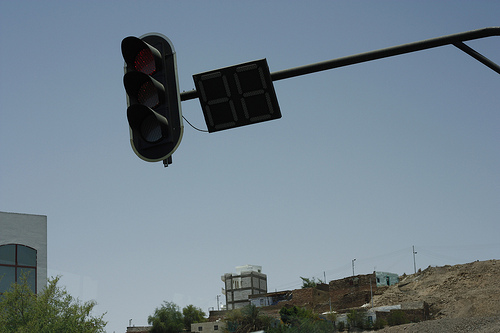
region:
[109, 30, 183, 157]
row of three lights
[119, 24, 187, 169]
black cones around the lights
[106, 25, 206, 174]
traffic light on a pole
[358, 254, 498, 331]
dirt on the ground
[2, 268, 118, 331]
top of a tree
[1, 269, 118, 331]
green leaves on the tree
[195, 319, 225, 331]
two small windows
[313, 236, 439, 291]
power lines on top of the incline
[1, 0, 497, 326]
no clouds visible in the sky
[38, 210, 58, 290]
corner of the building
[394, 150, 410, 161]
part of the sky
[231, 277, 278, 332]
part of a house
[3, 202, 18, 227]
side of a wall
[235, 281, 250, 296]
side of a building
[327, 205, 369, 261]
part of a cloud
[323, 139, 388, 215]
part of a cloud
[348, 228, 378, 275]
[art f a cloud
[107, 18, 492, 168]
pole with traffic lights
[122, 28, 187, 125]
three traffic lights on panel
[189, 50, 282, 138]
panel for lit numbers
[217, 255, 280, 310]
building on elevated terrain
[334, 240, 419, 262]
utility lines strung between poles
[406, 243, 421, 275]
poles with utility lines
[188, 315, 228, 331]
building at base of elevated terrain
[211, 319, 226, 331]
window in the building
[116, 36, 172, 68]
the light is red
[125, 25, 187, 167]
the light is black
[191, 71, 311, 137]
the sign is black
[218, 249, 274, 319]
the building is white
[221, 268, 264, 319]
the building is tall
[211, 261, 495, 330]
the hill is dirt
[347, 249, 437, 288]
electric poles on hill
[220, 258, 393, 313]
Building on top of hill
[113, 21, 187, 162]
street light on pole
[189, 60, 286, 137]
Metal sign on pole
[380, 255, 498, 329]
Hill with exposed dirt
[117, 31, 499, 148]
trafic light on end of pole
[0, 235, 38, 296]
window on white building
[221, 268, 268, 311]
White building on hillside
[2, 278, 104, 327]
tree in front of white building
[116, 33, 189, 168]
traffic light near metal sign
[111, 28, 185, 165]
A traffic light is on the pole.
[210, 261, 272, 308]
A large building by the traffic light.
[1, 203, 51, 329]
A large building by the traffic light.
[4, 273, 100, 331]
A green tree by the large building.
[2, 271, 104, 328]
A green tree by the large building.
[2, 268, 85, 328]
A green tree by the large building.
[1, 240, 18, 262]
a window on a building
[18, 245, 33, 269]
a window on a building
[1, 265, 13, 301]
a window on a building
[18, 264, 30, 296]
a window on a building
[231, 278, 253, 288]
a window on a building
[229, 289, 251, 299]
a window on a building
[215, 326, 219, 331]
a window on a building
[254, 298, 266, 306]
a window on a building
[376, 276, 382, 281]
a window on a building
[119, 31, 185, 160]
black traffic light on black pole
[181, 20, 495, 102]
black pole where traffic light is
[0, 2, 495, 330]
light blue clear sky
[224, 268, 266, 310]
black and white small building in the background